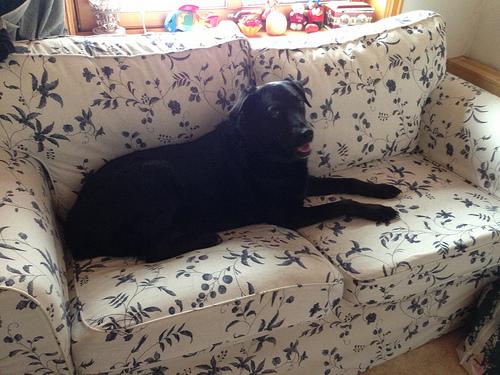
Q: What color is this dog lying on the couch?
A: Black.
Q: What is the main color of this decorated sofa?
A: White.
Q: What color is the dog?
A: Black.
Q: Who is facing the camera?
A: The dog.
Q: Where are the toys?
A: On the window.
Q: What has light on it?
A: The window.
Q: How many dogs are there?
A: One.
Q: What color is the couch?
A: White and blue.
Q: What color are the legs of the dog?
A: Black.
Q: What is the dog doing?
A: Laying down.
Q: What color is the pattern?
A: Grey and white.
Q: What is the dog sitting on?
A: Couch.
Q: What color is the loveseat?
A: Black and white.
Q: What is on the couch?
A: Lab.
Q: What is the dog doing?
A: Laying down.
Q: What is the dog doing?
A: Panting.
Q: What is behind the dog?
A: Small objects.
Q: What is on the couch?
A: Black dog.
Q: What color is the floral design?
A: Black.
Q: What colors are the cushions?
A: Black and white.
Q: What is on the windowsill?
A: Knick knacks.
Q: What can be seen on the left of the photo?
A: An armrest of a couch.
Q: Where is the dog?
A: On the couch.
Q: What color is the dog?
A: Black.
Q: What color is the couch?
A: White.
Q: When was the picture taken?
A: Daytime.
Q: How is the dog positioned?
A: Laying down.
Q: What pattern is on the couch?
A: Flowers.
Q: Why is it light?
A: The sun is coming through the window.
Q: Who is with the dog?
A: Nobody.